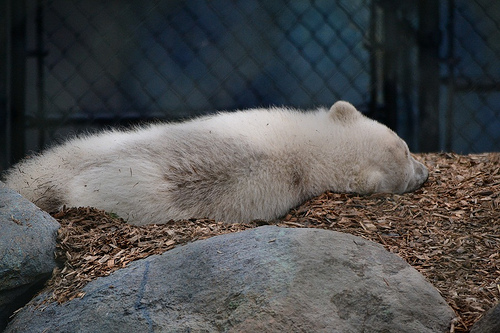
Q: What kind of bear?
A: White.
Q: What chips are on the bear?
A: Wood.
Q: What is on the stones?
A: Wood chips.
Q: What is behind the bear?
A: Fence.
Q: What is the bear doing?
A: Sleeping.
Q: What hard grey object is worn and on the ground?
A: Rock.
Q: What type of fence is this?
A: Chain linked.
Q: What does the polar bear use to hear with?
A: Ears.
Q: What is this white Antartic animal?
A: Polar bear.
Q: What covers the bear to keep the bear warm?
A: Hair.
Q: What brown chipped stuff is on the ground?
A: Mulch.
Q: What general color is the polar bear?
A: White.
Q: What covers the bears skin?
A: Fur.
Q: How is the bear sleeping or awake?
A: Sleeping.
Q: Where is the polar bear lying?
A: Ground.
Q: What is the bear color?
A: White.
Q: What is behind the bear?
A: Fence.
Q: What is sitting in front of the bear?
A: Rock.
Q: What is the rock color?
A: Gray.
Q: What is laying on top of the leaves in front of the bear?
A: Rock.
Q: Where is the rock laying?
A: Front of bear.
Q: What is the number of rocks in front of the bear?
A: One.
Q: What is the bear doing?
A: Sleeping.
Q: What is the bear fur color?
A: White.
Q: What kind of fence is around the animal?
A: Chain link.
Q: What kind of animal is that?
A: A polar bear.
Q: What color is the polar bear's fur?
A: White.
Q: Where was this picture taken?
A: At the zoo.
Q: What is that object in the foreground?
A: A rock.